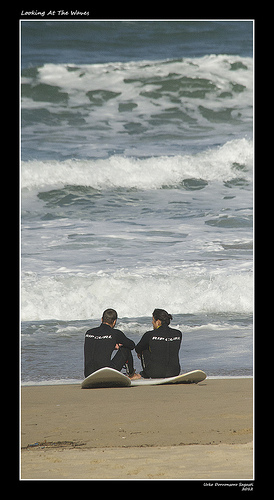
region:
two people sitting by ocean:
[81, 299, 216, 408]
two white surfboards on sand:
[68, 359, 209, 391]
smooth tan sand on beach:
[36, 386, 239, 451]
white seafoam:
[62, 258, 202, 317]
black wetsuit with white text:
[87, 319, 126, 376]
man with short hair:
[98, 311, 117, 327]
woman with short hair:
[144, 302, 173, 329]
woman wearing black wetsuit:
[139, 304, 192, 383]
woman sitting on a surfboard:
[131, 303, 194, 390]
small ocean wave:
[66, 37, 211, 120]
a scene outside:
[23, 25, 254, 489]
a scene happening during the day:
[8, 3, 261, 490]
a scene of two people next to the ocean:
[13, 18, 257, 487]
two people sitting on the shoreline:
[79, 296, 214, 404]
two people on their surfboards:
[62, 303, 215, 405]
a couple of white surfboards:
[64, 355, 213, 413]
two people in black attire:
[78, 305, 191, 386]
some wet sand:
[18, 377, 269, 478]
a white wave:
[27, 265, 272, 322]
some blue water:
[21, 21, 253, 59]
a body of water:
[38, 40, 158, 147]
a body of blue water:
[92, 219, 230, 267]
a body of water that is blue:
[67, 176, 219, 255]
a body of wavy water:
[75, 185, 249, 293]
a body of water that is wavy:
[28, 135, 256, 323]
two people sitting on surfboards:
[52, 275, 237, 429]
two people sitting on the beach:
[69, 290, 272, 453]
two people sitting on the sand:
[68, 266, 227, 418]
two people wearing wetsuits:
[61, 288, 243, 433]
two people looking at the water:
[53, 277, 266, 477]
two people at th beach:
[85, 304, 191, 383]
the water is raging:
[55, 137, 211, 302]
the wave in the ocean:
[39, 147, 235, 192]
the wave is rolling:
[24, 149, 150, 190]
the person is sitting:
[84, 306, 137, 380]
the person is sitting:
[138, 300, 186, 377]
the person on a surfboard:
[78, 309, 132, 379]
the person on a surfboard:
[142, 294, 188, 375]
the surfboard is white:
[77, 362, 141, 396]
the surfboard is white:
[135, 366, 221, 391]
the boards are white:
[84, 359, 210, 397]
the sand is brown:
[68, 394, 210, 431]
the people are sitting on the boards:
[77, 295, 210, 398]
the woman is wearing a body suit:
[144, 323, 181, 373]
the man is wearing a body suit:
[82, 321, 134, 368]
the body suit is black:
[81, 322, 135, 373]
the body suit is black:
[141, 323, 187, 374]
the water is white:
[48, 298, 80, 313]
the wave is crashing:
[124, 262, 230, 299]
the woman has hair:
[157, 307, 171, 321]